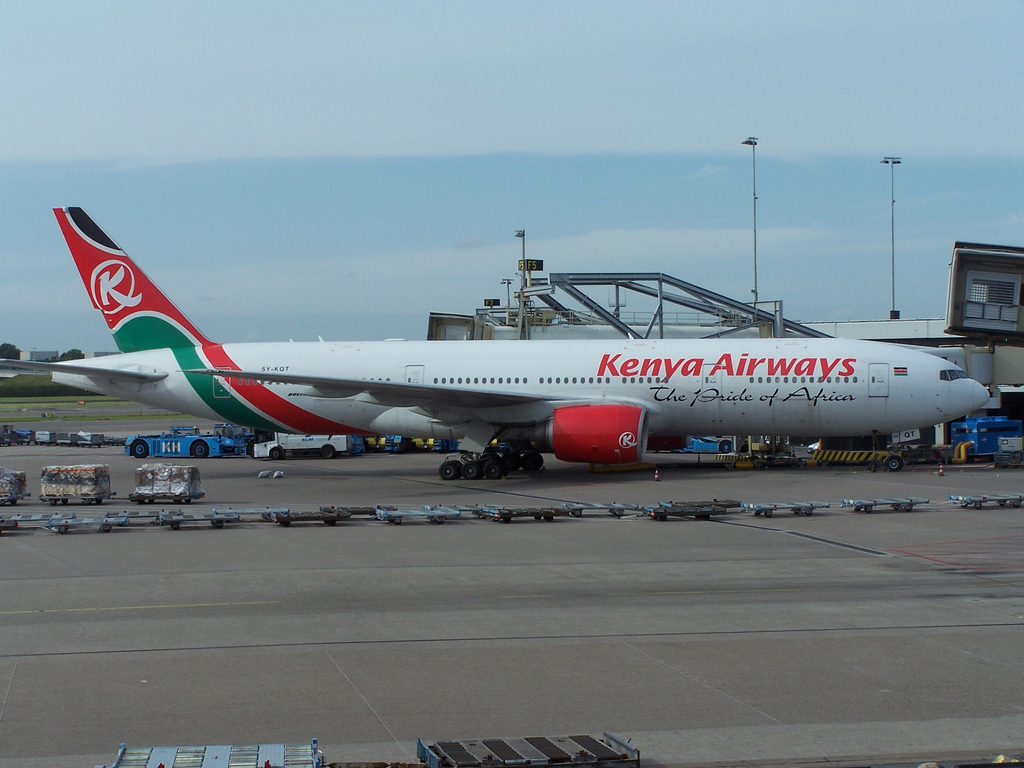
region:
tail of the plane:
[42, 203, 170, 344]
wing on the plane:
[52, 348, 166, 393]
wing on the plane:
[266, 361, 381, 385]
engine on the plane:
[571, 402, 658, 444]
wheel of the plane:
[463, 454, 515, 481]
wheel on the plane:
[879, 439, 952, 468]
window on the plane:
[443, 376, 473, 384]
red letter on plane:
[619, 351, 639, 378]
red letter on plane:
[635, 357, 664, 377]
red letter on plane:
[661, 350, 680, 383]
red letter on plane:
[683, 354, 707, 373]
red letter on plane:
[710, 347, 742, 379]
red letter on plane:
[762, 351, 795, 378]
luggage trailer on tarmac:
[431, 725, 640, 764]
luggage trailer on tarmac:
[738, 495, 824, 515]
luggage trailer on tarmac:
[942, 482, 1019, 511]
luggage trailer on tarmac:
[648, 495, 729, 522]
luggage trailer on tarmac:
[560, 495, 631, 518]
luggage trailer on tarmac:
[479, 495, 556, 524]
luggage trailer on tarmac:
[371, 501, 458, 522]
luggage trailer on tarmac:
[273, 502, 353, 529]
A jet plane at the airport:
[5, 206, 996, 504]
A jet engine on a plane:
[502, 402, 661, 463]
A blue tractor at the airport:
[120, 428, 247, 464]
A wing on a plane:
[179, 348, 660, 443]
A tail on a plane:
[52, 205, 218, 348]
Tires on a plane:
[435, 450, 508, 490]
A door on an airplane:
[865, 351, 888, 406]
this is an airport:
[157, 177, 932, 709]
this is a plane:
[61, 212, 701, 589]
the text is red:
[497, 315, 1020, 434]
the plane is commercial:
[172, 271, 1011, 610]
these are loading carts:
[40, 420, 426, 557]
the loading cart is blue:
[81, 399, 233, 483]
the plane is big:
[5, 204, 996, 486]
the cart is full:
[127, 460, 207, 502]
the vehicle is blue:
[119, 421, 253, 461]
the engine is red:
[544, 400, 652, 467]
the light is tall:
[740, 130, 764, 304]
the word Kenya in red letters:
[596, 345, 705, 390]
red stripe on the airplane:
[208, 346, 260, 389]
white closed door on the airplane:
[871, 361, 891, 404]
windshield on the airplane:
[941, 367, 977, 388]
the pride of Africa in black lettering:
[647, 383, 864, 412]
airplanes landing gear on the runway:
[442, 449, 551, 482]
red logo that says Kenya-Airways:
[602, 344, 868, 384]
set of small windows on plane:
[428, 368, 528, 387]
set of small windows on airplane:
[744, 373, 863, 392]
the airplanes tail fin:
[49, 189, 230, 354]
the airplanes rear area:
[7, 178, 353, 455]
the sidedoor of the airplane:
[397, 358, 424, 407]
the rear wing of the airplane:
[7, 345, 172, 387]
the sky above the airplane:
[13, 9, 1012, 379]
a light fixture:
[719, 107, 787, 307]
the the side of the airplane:
[65, 335, 928, 419]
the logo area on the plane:
[78, 256, 158, 323]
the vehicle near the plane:
[119, 426, 241, 464]